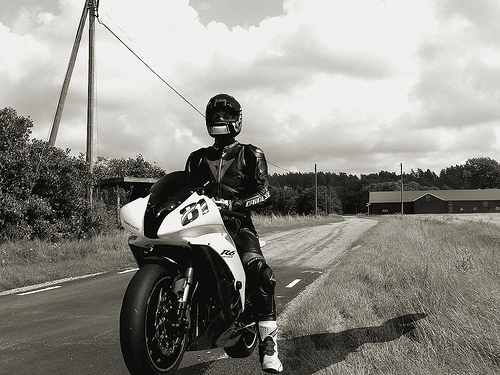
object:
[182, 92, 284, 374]
man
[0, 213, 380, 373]
road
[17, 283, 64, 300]
line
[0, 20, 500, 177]
sky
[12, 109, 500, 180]
tops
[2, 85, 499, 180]
horizon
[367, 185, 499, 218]
building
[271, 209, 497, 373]
grass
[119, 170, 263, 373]
motorcycle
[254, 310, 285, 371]
boot